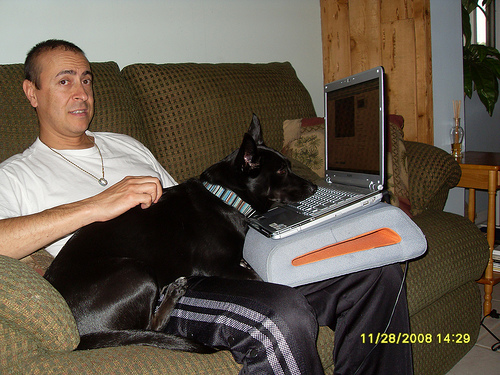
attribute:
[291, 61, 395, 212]
laptop — silver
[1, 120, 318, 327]
dog — black, shiny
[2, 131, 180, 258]
t-shirt — white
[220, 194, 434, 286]
stand — cushioned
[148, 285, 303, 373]
stripes — on side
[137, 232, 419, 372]
pants — man's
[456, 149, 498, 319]
table — brown, wood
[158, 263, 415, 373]
pants — man's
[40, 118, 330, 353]
dog — dark 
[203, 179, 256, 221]
collar — multicolored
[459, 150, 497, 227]
table — small, wooden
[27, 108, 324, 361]
dog — sitting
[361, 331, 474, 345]
stamp — yellow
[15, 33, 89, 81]
hair — short